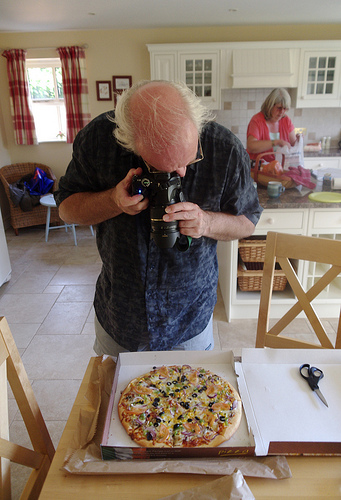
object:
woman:
[247, 86, 304, 179]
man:
[54, 77, 261, 355]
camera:
[131, 171, 191, 248]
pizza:
[118, 363, 243, 448]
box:
[100, 349, 256, 458]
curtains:
[58, 46, 91, 144]